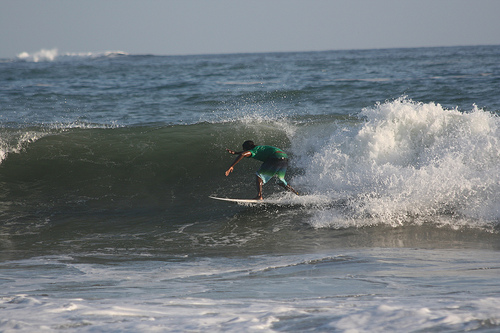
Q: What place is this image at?
A: It is at the ocean.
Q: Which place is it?
A: It is an ocean.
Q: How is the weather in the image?
A: It is overcast.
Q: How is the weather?
A: It is overcast.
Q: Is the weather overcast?
A: Yes, it is overcast.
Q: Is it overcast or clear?
A: It is overcast.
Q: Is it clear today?
A: No, it is overcast.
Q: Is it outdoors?
A: Yes, it is outdoors.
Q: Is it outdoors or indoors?
A: It is outdoors.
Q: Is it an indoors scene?
A: No, it is outdoors.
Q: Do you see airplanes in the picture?
A: No, there are no airplanes.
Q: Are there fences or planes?
A: No, there are no planes or fences.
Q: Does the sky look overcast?
A: Yes, the sky is overcast.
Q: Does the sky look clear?
A: No, the sky is overcast.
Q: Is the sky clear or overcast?
A: The sky is overcast.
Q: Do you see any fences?
A: No, there are no fences.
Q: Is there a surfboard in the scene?
A: Yes, there is a surfboard.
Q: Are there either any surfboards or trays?
A: Yes, there is a surfboard.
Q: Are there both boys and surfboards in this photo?
A: Yes, there are both a surfboard and a boy.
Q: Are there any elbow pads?
A: No, there are no elbow pads.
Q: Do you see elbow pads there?
A: No, there are no elbow pads.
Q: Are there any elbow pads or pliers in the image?
A: No, there are no elbow pads or pliers.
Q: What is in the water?
A: The surfboard is in the water.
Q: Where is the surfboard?
A: The surfboard is in the water.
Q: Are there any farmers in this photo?
A: No, there are no farmers.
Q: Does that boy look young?
A: Yes, the boy is young.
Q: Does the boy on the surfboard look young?
A: Yes, the boy is young.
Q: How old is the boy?
A: The boy is young.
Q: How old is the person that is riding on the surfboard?
A: The boy is young.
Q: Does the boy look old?
A: No, the boy is young.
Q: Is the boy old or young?
A: The boy is young.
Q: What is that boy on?
A: The boy is on the surfboard.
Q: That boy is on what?
A: The boy is on the surfboard.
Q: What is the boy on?
A: The boy is on the surfboard.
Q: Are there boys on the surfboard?
A: Yes, there is a boy on the surfboard.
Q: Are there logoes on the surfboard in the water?
A: No, there is a boy on the surf board.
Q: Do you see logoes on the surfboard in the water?
A: No, there is a boy on the surf board.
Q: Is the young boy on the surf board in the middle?
A: Yes, the boy is on the surfboard.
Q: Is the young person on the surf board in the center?
A: Yes, the boy is on the surfboard.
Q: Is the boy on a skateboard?
A: No, the boy is on the surfboard.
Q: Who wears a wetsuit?
A: The boy wears a wetsuit.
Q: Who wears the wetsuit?
A: The boy wears a wetsuit.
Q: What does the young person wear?
A: The boy wears a wet suit.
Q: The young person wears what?
A: The boy wears a wet suit.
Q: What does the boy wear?
A: The boy wears a wet suit.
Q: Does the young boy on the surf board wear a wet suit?
A: Yes, the boy wears a wet suit.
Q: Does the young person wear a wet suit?
A: Yes, the boy wears a wet suit.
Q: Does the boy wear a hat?
A: No, the boy wears a wet suit.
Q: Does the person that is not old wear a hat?
A: No, the boy wears a wet suit.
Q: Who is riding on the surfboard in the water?
A: The boy is riding on the surfboard.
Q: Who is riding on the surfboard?
A: The boy is riding on the surfboard.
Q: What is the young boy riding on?
A: The boy is riding on the surfboard.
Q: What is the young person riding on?
A: The boy is riding on the surfboard.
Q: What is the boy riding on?
A: The boy is riding on the surfboard.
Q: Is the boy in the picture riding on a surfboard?
A: Yes, the boy is riding on a surfboard.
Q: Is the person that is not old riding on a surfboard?
A: Yes, the boy is riding on a surfboard.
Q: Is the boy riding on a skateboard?
A: No, the boy is riding on a surfboard.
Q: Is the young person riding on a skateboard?
A: No, the boy is riding on a surfboard.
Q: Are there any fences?
A: No, there are no fences.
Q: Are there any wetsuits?
A: Yes, there is a wetsuit.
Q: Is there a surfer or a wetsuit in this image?
A: Yes, there is a wetsuit.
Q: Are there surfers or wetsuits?
A: Yes, there is a wetsuit.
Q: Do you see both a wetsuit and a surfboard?
A: Yes, there are both a wetsuit and a surfboard.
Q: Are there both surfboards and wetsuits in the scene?
A: Yes, there are both a wetsuit and a surfboard.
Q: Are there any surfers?
A: Yes, there is a surfer.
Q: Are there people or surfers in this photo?
A: Yes, there is a surfer.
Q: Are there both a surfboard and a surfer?
A: Yes, there are both a surfer and a surfboard.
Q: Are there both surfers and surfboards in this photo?
A: Yes, there are both a surfer and a surfboard.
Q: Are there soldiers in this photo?
A: No, there are no soldiers.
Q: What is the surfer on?
A: The surfer is on the surf board.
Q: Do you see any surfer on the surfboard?
A: Yes, there is a surfer on the surfboard.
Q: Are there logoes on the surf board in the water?
A: No, there is a surfer on the surfboard.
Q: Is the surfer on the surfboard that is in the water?
A: Yes, the surfer is on the surf board.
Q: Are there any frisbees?
A: No, there are no frisbees.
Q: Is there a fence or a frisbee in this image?
A: No, there are no frisbees or fences.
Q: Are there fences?
A: No, there are no fences.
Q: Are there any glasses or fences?
A: No, there are no fences or glasses.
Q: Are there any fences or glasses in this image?
A: No, there are no fences or glasses.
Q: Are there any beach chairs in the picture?
A: No, there are no beach chairs.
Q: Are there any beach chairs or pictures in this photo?
A: No, there are no beach chairs or pictures.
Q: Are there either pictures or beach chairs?
A: No, there are no beach chairs or pictures.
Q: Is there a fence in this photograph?
A: No, there are no fences.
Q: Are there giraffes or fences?
A: No, there are no fences or giraffes.